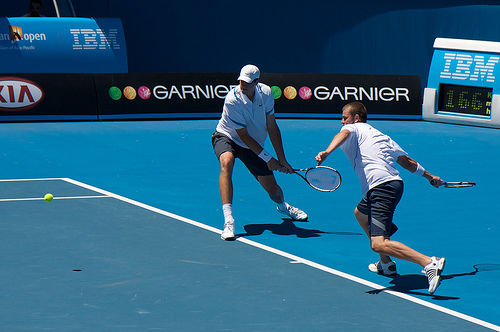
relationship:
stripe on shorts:
[369, 214, 392, 232] [356, 177, 403, 235]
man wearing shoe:
[312, 106, 448, 298] [421, 256, 446, 296]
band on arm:
[416, 161, 425, 179] [398, 155, 445, 185]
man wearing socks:
[210, 63, 308, 243] [222, 199, 234, 219]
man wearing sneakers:
[210, 63, 308, 243] [222, 223, 238, 243]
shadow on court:
[365, 257, 479, 300] [3, 119, 499, 329]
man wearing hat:
[210, 63, 308, 243] [234, 63, 259, 83]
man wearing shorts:
[312, 106, 448, 298] [352, 179, 401, 237]